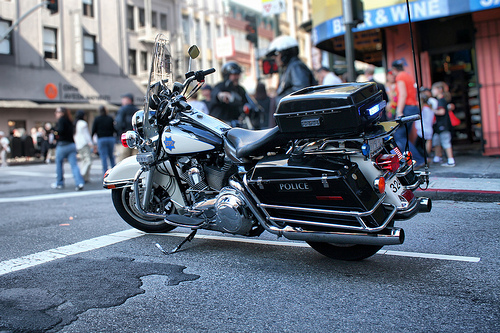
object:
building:
[1, 0, 317, 151]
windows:
[0, 0, 171, 78]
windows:
[180, 0, 222, 85]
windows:
[231, 27, 273, 59]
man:
[265, 33, 320, 109]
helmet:
[264, 35, 299, 68]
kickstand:
[154, 226, 202, 255]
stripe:
[0, 228, 147, 281]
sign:
[308, 0, 500, 48]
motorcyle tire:
[299, 206, 395, 261]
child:
[426, 81, 461, 167]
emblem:
[163, 135, 176, 151]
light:
[374, 153, 400, 172]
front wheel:
[111, 183, 194, 234]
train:
[44, 82, 111, 102]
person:
[50, 106, 86, 191]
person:
[89, 104, 118, 180]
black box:
[272, 81, 389, 140]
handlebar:
[179, 67, 216, 100]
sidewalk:
[402, 150, 498, 179]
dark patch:
[0, 255, 203, 332]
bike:
[101, 32, 433, 261]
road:
[0, 171, 500, 333]